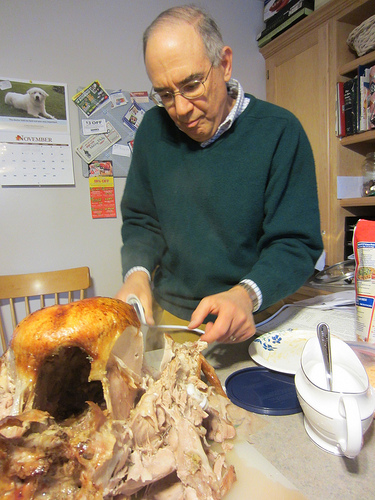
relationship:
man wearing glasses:
[113, 7, 323, 350] [144, 58, 217, 108]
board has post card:
[79, 84, 163, 187] [74, 80, 106, 118]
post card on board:
[74, 80, 106, 118] [79, 84, 163, 187]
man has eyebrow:
[113, 7, 323, 350] [152, 83, 172, 94]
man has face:
[113, 7, 323, 350] [150, 63, 219, 142]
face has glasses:
[150, 63, 219, 142] [144, 58, 217, 108]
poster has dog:
[2, 80, 75, 190] [5, 86, 59, 121]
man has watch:
[113, 7, 323, 350] [235, 279, 259, 310]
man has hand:
[113, 7, 323, 350] [191, 284, 260, 348]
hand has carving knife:
[118, 270, 156, 323] [127, 290, 148, 329]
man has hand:
[113, 7, 323, 350] [118, 270, 156, 323]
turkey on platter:
[5, 296, 233, 500] [2, 357, 214, 500]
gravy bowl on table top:
[299, 335, 374, 462] [140, 298, 369, 498]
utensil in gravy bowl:
[310, 321, 338, 393] [299, 335, 374, 462]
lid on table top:
[223, 362, 309, 417] [140, 298, 369, 498]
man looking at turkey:
[113, 7, 323, 350] [5, 296, 233, 500]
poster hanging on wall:
[2, 80, 75, 190] [2, 2, 287, 345]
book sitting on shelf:
[337, 79, 346, 137] [338, 126, 374, 147]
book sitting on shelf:
[343, 75, 355, 133] [338, 126, 374, 147]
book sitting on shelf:
[357, 63, 371, 135] [338, 126, 374, 147]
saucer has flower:
[247, 326, 318, 378] [262, 338, 277, 354]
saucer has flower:
[247, 326, 318, 378] [270, 332, 285, 347]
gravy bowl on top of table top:
[299, 335, 374, 462] [140, 298, 369, 498]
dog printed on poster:
[5, 86, 59, 121] [2, 80, 75, 190]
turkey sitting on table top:
[5, 296, 233, 500] [140, 298, 369, 498]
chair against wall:
[0, 267, 93, 347] [2, 2, 287, 345]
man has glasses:
[113, 7, 323, 350] [144, 58, 217, 108]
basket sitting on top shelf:
[345, 12, 375, 56] [341, 49, 374, 74]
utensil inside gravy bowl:
[310, 321, 338, 393] [299, 335, 374, 462]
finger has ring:
[224, 321, 247, 344] [230, 334, 239, 344]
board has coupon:
[79, 84, 163, 187] [82, 118, 109, 136]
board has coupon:
[79, 84, 163, 187] [88, 160, 121, 223]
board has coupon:
[79, 84, 163, 187] [76, 124, 125, 160]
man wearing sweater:
[113, 7, 323, 350] [118, 94, 321, 323]